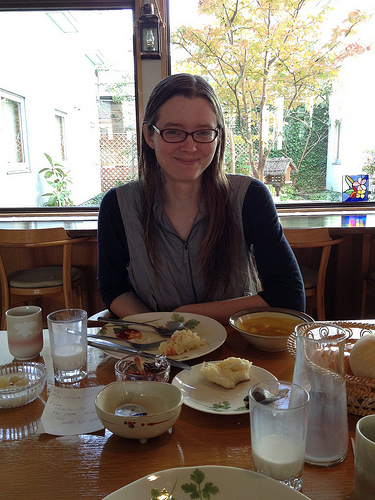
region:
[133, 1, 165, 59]
lantern light fixture on the wall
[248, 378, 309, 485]
partially drank glass of milk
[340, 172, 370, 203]
flower stain glass window decoration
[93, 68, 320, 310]
smiling woman with long brown hair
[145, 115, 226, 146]
black glasses the woman is wearing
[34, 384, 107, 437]
the check for the meal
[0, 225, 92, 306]
chair at the window counter behind the smiling woman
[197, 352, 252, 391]
left over bread sitting on a plate in front of the woman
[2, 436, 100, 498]
brown wooden table the woman is dining at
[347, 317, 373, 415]
basket with untouched bread from the meal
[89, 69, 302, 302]
this is a lady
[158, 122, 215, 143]
she is wearing spectacles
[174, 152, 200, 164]
the mouth is closed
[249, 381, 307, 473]
this is a glass of milk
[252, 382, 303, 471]
the glass is quarterly with milk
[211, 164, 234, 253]
the hair is long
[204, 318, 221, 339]
this is a plate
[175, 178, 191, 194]
the lady is light skinned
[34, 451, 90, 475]
the table is wooden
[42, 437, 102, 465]
the table is brown in color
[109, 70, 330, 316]
The woman is sitting at the table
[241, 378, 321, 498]
Glass of milk on table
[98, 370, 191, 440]
bowl with clear soup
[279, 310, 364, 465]
A pitcher that has milk residue in it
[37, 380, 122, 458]
Note sitting on the table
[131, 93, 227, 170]
Woman wearing black framed glasses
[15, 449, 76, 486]
The table is light and wooden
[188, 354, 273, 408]
Eaten biscuit on plate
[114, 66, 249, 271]
The woman has long brown hair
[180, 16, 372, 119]
Tree outside the window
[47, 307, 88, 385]
glass cup of milk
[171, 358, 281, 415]
a saucer with a leaf print on it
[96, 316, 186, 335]
a spoon on a plate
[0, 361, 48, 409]
a glass bowl with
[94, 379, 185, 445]
a ceramic bowel with a design on it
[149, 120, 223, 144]
a woman wearing glasses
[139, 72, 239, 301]
a woman with long brown hair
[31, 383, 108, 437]
a white piece of paper with writing on it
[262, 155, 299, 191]
a bird house with a straw roof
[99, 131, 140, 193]
a fence outside the window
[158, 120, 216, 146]
a pair of glasses on the woman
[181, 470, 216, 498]
a green leaf on the plate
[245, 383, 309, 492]
a glass with milk in it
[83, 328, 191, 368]
a case knife on the plate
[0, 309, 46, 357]
a coffee cup on the table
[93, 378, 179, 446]
a white glass bowl on the table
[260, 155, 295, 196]
a birdhouse outside the window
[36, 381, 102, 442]
a white piece of paper on the table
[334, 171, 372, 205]
a colorful piece of stain glass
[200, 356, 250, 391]
a half ate biscuit on the table